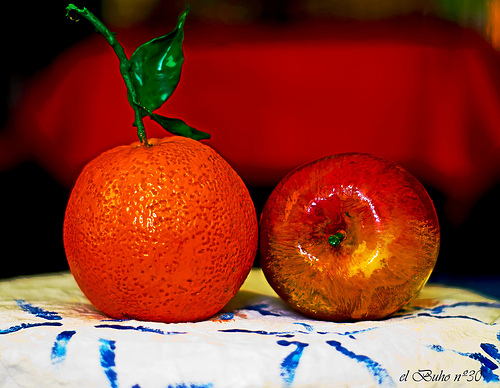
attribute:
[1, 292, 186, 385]
design — blue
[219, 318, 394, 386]
design — blue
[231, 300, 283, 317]
design — blue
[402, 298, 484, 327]
design — blue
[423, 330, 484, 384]
design — blue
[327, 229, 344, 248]
stem — green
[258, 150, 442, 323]
apple — yellow, red, small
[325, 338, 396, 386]
line — blue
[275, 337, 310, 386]
line — blue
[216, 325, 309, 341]
line — blue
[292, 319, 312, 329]
line — blue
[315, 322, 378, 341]
line — blue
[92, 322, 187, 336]
line — blue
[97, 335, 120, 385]
line — blue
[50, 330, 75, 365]
line — blue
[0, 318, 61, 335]
line — blue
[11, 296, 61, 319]
line — blue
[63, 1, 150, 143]
stem — green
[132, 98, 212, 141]
leaf — small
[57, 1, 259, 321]
orange — medium sized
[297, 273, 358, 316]
part — rotting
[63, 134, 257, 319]
circle — orange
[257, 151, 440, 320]
circle — red, yellow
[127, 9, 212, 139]
leaves — green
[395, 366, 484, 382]
logo — white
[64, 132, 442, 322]
fruits — different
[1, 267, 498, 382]
surface — blue, white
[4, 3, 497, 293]
background — blurry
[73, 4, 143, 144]
stem — green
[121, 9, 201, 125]
leaf — dark green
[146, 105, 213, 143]
leaf — dark green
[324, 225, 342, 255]
stem — green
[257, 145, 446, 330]
fruit — red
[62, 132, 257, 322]
fruit — orange, dark orange colored orange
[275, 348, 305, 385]
line — blue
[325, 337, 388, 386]
line — blue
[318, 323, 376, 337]
line — blue